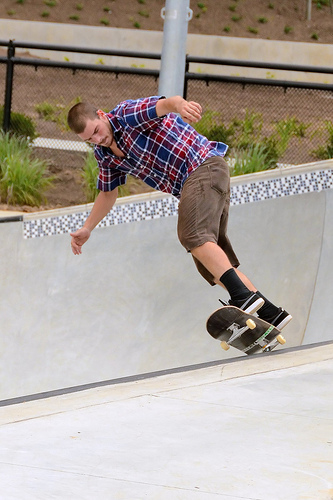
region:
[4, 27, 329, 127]
a black fence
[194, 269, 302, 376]
a skateboard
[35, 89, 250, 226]
a man in a plaid shirt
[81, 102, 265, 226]
a red white and blue plaid shirt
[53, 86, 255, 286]
a man in shorts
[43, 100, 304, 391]
a man skateboarding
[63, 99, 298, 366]
a man wearing black socks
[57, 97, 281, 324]
a man wearing black sneakers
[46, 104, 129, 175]
a man with facial hair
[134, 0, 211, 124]
a silver metal pole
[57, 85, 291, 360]
a man riding a skateboard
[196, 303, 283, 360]
a black skateboard with yellow wheels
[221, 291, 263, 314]
a black and white shoe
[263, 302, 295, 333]
a black and white shoe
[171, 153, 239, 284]
men's short brown pants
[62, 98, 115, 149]
man's face with facial hair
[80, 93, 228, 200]
blue red and white striped shirt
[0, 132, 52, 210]
patch of green grass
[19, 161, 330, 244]
black and white decorative tile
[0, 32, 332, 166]
black metal fencing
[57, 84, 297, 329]
A man wearing a blue and red shirt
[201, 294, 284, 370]
A skateboard with three wheels off the ground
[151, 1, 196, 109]
Part of a metal pole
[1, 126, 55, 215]
Part of a green bush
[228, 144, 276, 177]
A green bush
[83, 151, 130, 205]
part of a green bush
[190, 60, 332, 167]
Part of a fence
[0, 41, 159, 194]
part of a fence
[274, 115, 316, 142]
a green bush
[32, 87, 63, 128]
a green bush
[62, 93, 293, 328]
man riding skateboard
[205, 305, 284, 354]
black skateboard with white wheels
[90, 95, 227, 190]
short-sleeve plaid shirt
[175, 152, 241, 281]
long brown shorts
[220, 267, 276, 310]
black socks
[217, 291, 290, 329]
black and white shoes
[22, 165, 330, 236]
black and white tile trim at edge of pool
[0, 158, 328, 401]
concrete pool with no water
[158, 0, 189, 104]
silver pole in background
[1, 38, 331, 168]
black fence in background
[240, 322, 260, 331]
wheel of a skate board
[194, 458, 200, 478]
part of a court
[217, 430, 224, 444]
bottom of a surface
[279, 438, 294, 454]
edge of a court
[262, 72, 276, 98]
edge of a fence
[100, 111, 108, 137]
face of a man